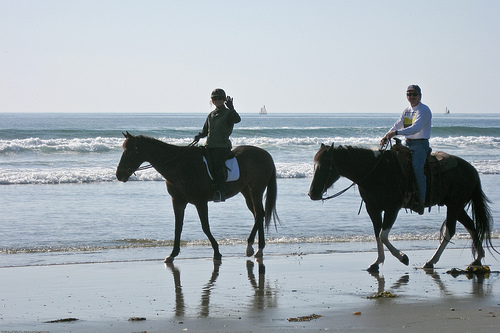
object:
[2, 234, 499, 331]
beach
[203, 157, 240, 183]
mat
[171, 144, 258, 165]
horse back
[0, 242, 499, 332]
sand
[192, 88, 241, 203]
woman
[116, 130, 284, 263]
horse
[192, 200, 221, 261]
leg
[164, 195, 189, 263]
leg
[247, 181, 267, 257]
leg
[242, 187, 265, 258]
leg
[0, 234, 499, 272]
coastline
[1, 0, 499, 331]
photo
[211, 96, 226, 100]
eyeglasses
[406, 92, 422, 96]
eyeglasses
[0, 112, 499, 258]
water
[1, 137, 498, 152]
waves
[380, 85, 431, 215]
man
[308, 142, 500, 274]
horse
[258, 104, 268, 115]
boat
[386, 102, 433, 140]
shirt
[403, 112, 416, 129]
design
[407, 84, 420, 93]
baseball cap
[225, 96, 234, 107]
hand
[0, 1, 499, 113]
sky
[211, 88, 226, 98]
helmet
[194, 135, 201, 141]
hand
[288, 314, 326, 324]
tracks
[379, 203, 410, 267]
leg